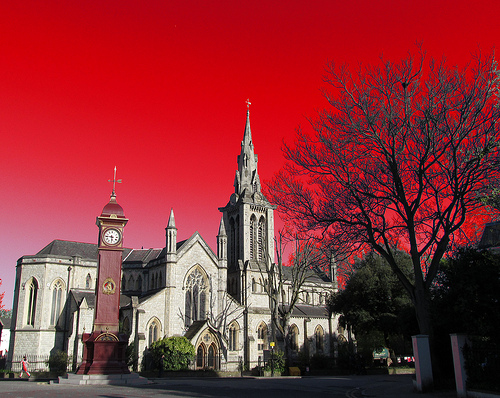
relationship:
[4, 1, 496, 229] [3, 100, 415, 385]
sky above church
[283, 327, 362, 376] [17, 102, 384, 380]
shadows on church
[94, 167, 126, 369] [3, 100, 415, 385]
tower on church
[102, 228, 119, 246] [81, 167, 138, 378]
clock on tower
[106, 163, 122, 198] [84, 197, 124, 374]
cross on tower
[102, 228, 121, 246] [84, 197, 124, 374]
clock on tower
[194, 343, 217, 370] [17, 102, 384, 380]
double doors on church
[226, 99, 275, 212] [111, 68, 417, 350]
steeple on church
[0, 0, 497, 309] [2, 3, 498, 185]
clouds in sky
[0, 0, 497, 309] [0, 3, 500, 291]
clouds in red sky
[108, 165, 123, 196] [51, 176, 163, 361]
cross on tower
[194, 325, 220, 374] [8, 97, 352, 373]
entrance to church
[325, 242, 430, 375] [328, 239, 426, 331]
tree with leaves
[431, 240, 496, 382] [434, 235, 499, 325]
tree with leaves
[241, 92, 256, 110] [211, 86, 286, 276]
cross on church tower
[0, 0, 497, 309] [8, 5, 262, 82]
clouds in sky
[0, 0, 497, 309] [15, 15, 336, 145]
clouds in sky